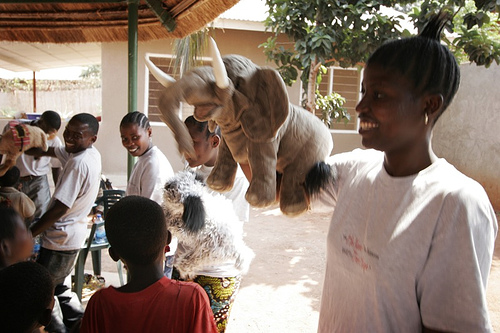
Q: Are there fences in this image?
A: No, there are no fences.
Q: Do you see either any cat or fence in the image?
A: No, there are no fences or cats.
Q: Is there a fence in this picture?
A: No, there are no fences.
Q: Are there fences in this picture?
A: No, there are no fences.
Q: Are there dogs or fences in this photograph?
A: No, there are no fences or dogs.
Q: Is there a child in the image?
A: Yes, there is a child.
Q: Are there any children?
A: Yes, there is a child.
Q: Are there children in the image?
A: Yes, there is a child.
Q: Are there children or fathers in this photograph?
A: Yes, there is a child.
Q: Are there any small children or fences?
A: Yes, there is a small child.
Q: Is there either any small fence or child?
A: Yes, there is a small child.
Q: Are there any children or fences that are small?
A: Yes, the child is small.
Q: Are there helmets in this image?
A: No, there are no helmets.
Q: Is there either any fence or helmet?
A: No, there are no helmets or fences.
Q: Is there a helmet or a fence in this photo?
A: No, there are no helmets or fences.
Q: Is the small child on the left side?
A: Yes, the kid is on the left of the image.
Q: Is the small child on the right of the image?
A: No, the kid is on the left of the image.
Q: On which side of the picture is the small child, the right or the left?
A: The child is on the left of the image.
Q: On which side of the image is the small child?
A: The child is on the left of the image.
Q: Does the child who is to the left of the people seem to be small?
A: Yes, the kid is small.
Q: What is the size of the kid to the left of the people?
A: The kid is small.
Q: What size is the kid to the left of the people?
A: The kid is small.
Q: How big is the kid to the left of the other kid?
A: The kid is small.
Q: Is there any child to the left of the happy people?
A: Yes, there is a child to the left of the people.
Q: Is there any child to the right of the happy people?
A: No, the child is to the left of the people.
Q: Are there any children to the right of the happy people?
A: No, the child is to the left of the people.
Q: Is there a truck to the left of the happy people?
A: No, there is a child to the left of the people.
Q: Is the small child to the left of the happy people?
A: Yes, the kid is to the left of the people.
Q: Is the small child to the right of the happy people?
A: No, the child is to the left of the people.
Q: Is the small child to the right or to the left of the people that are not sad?
A: The child is to the left of the people.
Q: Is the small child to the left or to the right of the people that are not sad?
A: The child is to the left of the people.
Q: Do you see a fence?
A: No, there are no fences.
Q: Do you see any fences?
A: No, there are no fences.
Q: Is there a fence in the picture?
A: No, there are no fences.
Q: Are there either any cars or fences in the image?
A: No, there are no fences or cars.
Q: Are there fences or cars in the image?
A: No, there are no fences or cars.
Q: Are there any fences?
A: No, there are no fences.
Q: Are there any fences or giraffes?
A: No, there are no fences or giraffes.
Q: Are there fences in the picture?
A: No, there are no fences.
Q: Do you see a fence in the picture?
A: No, there are no fences.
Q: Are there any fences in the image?
A: No, there are no fences.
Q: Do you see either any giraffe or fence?
A: No, there are no fences or giraffes.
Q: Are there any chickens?
A: No, there are no chickens.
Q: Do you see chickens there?
A: No, there are no chickens.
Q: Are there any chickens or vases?
A: No, there are no chickens or vases.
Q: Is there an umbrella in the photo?
A: Yes, there is an umbrella.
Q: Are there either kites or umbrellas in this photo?
A: Yes, there is an umbrella.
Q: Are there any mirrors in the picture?
A: No, there are no mirrors.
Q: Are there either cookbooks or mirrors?
A: No, there are no mirrors or cookbooks.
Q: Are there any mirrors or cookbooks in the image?
A: No, there are no mirrors or cookbooks.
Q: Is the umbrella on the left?
A: Yes, the umbrella is on the left of the image.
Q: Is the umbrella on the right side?
A: No, the umbrella is on the left of the image.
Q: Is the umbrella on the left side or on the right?
A: The umbrella is on the left of the image.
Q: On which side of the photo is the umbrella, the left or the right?
A: The umbrella is on the left of the image.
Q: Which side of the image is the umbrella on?
A: The umbrella is on the left of the image.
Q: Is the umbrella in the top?
A: Yes, the umbrella is in the top of the image.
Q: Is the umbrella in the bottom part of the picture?
A: No, the umbrella is in the top of the image.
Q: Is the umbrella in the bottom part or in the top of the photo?
A: The umbrella is in the top of the image.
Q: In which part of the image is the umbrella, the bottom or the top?
A: The umbrella is in the top of the image.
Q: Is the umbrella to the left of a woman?
A: Yes, the umbrella is to the left of a woman.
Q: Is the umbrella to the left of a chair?
A: No, the umbrella is to the left of a woman.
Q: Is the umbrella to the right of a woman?
A: No, the umbrella is to the left of a woman.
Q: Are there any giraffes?
A: No, there are no giraffes.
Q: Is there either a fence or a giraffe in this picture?
A: No, there are no giraffes or fences.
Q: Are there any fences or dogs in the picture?
A: No, there are no fences or dogs.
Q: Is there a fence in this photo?
A: No, there are no fences.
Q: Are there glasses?
A: No, there are no glasses.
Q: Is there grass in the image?
A: Yes, there is grass.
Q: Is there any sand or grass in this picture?
A: Yes, there is grass.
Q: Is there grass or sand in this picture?
A: Yes, there is grass.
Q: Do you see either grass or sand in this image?
A: Yes, there is grass.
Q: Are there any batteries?
A: No, there are no batteries.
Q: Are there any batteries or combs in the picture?
A: No, there are no batteries or combs.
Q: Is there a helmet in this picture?
A: No, there are no helmets.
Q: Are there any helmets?
A: No, there are no helmets.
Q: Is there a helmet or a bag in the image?
A: No, there are no helmets or bags.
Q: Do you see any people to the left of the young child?
A: Yes, there is a person to the left of the child.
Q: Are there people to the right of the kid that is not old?
A: No, the person is to the left of the kid.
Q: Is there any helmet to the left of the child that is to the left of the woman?
A: No, there is a person to the left of the kid.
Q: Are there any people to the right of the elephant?
A: No, the person is to the left of the elephant.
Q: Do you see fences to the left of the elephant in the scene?
A: No, there is a person to the left of the elephant.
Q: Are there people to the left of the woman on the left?
A: Yes, there is a person to the left of the woman.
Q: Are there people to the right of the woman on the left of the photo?
A: No, the person is to the left of the woman.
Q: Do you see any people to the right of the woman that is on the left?
A: No, the person is to the left of the woman.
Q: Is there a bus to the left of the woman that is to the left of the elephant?
A: No, there is a person to the left of the woman.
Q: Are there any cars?
A: No, there are no cars.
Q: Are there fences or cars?
A: No, there are no cars or fences.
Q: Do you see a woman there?
A: Yes, there is a woman.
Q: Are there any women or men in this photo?
A: Yes, there is a woman.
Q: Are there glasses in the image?
A: No, there are no glasses.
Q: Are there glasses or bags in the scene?
A: No, there are no glasses or bags.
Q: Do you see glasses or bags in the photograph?
A: No, there are no glasses or bags.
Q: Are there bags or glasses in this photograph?
A: No, there are no glasses or bags.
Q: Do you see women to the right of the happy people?
A: Yes, there is a woman to the right of the people.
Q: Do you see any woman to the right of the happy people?
A: Yes, there is a woman to the right of the people.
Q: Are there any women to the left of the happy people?
A: No, the woman is to the right of the people.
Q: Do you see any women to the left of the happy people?
A: No, the woman is to the right of the people.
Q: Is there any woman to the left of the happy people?
A: No, the woman is to the right of the people.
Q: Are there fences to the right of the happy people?
A: No, there is a woman to the right of the people.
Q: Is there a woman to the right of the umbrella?
A: Yes, there is a woman to the right of the umbrella.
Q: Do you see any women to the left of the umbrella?
A: No, the woman is to the right of the umbrella.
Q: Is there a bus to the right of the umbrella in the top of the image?
A: No, there is a woman to the right of the umbrella.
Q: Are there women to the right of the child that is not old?
A: Yes, there is a woman to the right of the child.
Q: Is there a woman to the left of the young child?
A: No, the woman is to the right of the kid.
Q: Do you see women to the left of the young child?
A: No, the woman is to the right of the kid.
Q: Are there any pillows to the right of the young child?
A: No, there is a woman to the right of the kid.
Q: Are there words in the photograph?
A: Yes, there are words.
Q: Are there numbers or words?
A: Yes, there are words.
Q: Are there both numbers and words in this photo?
A: No, there are words but no numbers.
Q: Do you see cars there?
A: No, there are no cars.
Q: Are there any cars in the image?
A: No, there are no cars.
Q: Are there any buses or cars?
A: No, there are no cars or buses.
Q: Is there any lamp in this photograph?
A: No, there are no lamps.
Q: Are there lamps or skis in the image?
A: No, there are no lamps or skis.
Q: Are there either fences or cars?
A: No, there are no fences or cars.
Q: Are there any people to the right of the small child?
A: Yes, there are people to the right of the kid.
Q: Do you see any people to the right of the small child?
A: Yes, there are people to the right of the kid.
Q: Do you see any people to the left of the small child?
A: No, the people are to the right of the child.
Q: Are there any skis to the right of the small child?
A: No, there are people to the right of the kid.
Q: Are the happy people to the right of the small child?
A: Yes, the people are to the right of the kid.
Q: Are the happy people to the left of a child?
A: No, the people are to the right of a child.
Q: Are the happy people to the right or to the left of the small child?
A: The people are to the right of the child.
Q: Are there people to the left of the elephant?
A: Yes, there are people to the left of the elephant.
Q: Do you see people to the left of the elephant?
A: Yes, there are people to the left of the elephant.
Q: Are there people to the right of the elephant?
A: No, the people are to the left of the elephant.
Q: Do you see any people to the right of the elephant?
A: No, the people are to the left of the elephant.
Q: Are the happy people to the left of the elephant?
A: Yes, the people are to the left of the elephant.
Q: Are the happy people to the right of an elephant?
A: No, the people are to the left of an elephant.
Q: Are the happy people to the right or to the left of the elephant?
A: The people are to the left of the elephant.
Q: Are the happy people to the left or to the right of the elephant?
A: The people are to the left of the elephant.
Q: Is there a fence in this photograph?
A: No, there are no fences.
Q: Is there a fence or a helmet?
A: No, there are no fences or helmets.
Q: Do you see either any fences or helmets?
A: No, there are no fences or helmets.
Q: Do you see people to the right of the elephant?
A: No, the person is to the left of the elephant.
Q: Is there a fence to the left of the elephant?
A: No, there is a person to the left of the elephant.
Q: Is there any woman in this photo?
A: Yes, there is a woman.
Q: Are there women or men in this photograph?
A: Yes, there is a woman.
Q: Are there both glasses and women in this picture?
A: No, there is a woman but no glasses.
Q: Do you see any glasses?
A: No, there are no glasses.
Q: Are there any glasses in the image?
A: No, there are no glasses.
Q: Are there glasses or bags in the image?
A: No, there are no glasses or bags.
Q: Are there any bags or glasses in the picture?
A: No, there are no glasses or bags.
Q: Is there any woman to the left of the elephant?
A: Yes, there is a woman to the left of the elephant.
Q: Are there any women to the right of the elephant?
A: No, the woman is to the left of the elephant.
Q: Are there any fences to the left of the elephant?
A: No, there is a woman to the left of the elephant.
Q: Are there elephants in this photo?
A: Yes, there is an elephant.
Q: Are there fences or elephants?
A: Yes, there is an elephant.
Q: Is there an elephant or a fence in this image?
A: Yes, there is an elephant.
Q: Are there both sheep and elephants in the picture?
A: No, there is an elephant but no sheep.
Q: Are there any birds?
A: No, there are no birds.